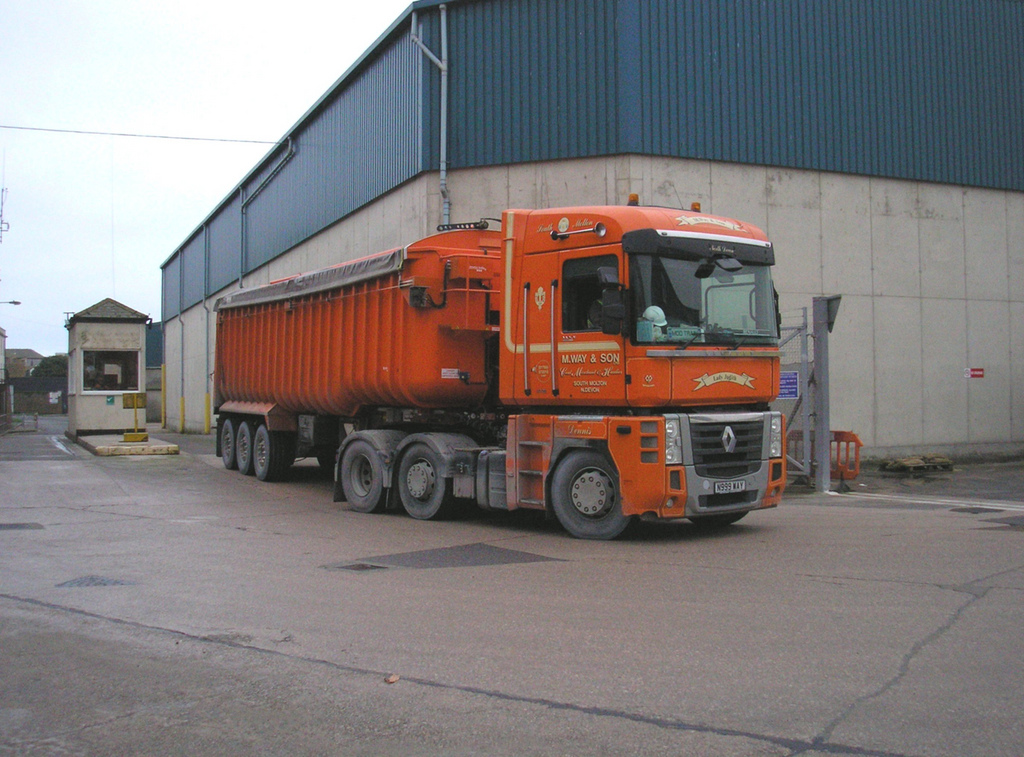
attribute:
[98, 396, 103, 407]
sign — green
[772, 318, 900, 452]
gate — grey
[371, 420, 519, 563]
tire — attached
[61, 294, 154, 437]
structure — small, tan, brown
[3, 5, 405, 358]
sky — blue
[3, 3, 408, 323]
cloud — white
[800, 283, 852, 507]
fence pole — metal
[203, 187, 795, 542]
truck — large, orange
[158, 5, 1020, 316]
roof — blue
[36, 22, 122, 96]
clouds — white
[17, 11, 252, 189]
sky — blue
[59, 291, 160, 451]
building — small, tan, brown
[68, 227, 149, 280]
clouds — white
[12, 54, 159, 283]
sky — blue